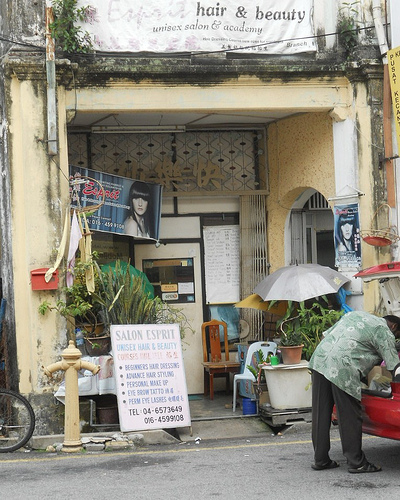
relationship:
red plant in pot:
[279, 333, 301, 346] [279, 344, 301, 362]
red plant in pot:
[42, 258, 111, 334] [84, 335, 110, 353]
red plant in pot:
[279, 333, 302, 346] [274, 334, 304, 364]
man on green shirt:
[302, 308, 397, 472] [305, 312, 398, 400]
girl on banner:
[122, 181, 153, 239] [68, 163, 164, 248]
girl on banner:
[122, 181, 153, 232] [68, 163, 164, 248]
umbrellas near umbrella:
[253, 262, 349, 305] [231, 291, 301, 319]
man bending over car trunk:
[302, 308, 397, 472] [361, 257, 399, 449]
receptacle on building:
[30, 268, 59, 291] [0, 0, 398, 436]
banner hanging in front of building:
[67, 164, 166, 248] [0, 0, 398, 436]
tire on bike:
[1, 386, 35, 451] [0, 381, 41, 457]